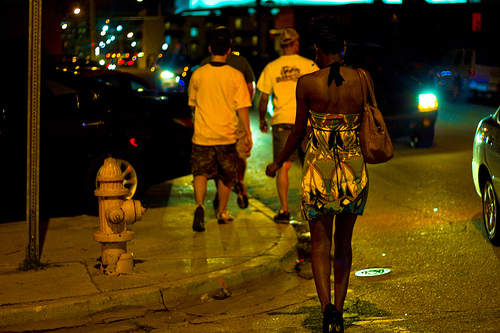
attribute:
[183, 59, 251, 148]
shirt — white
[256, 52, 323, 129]
shirt — white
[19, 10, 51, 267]
sign post — metal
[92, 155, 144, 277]
fire hydrant — yellow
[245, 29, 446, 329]
woman — walking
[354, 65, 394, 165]
purse — brown, leather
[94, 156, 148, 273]
hydrant — yellow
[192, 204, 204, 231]
sandal — black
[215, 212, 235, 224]
sandal — black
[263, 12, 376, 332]
woman — walking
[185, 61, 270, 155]
shirt — white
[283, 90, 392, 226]
sundress — green, yellow